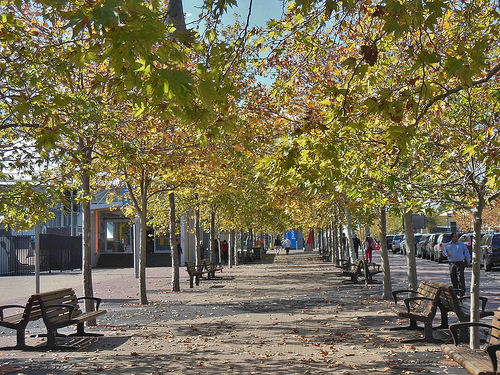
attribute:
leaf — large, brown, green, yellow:
[144, 67, 198, 108]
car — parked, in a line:
[416, 235, 430, 262]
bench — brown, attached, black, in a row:
[361, 259, 382, 283]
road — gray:
[350, 245, 499, 316]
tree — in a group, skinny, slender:
[339, 1, 428, 301]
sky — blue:
[184, 2, 372, 95]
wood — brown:
[35, 288, 106, 325]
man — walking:
[444, 231, 471, 293]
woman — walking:
[361, 236, 375, 264]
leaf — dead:
[364, 294, 380, 306]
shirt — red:
[223, 243, 230, 253]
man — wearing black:
[351, 232, 365, 258]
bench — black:
[340, 259, 360, 285]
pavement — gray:
[85, 251, 462, 374]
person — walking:
[280, 237, 293, 256]